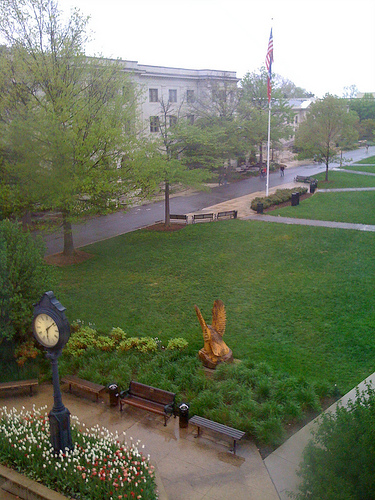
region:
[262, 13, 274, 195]
american flag at the top of a white flag pole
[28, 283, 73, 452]
clock in a park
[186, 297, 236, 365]
golden, winged sculpture in a park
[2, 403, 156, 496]
tiny pink, red, and white flowers near a clock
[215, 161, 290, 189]
people walking in the road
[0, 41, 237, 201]
trees partial obscuring a building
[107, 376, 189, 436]
two metal trash cans on either side of a wooden bench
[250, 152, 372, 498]
cement walkways throughout the park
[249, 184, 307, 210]
short, green bushes at the bottom of the flag pole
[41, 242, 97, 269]
wood chips around the base of a tree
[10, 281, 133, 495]
clock tower in flower bed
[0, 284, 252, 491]
park benches facing the tulips and clock tower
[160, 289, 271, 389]
gold American eagle statue in the park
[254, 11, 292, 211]
An American flag flying in the park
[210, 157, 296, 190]
people on campus walking to class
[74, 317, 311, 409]
landscape shrubs in the park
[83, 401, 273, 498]
the walkway is wet after rain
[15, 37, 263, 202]
large building on college campus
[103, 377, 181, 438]
ashtray next to the park bench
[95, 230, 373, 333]
green grass in the common area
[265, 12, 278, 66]
United States of America flag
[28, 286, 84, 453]
Black post with a clock at the top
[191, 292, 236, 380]
Wood carved eagle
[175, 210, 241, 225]
Row of benches on the sidewalk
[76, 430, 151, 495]
Flower bed with red, white and pink flowers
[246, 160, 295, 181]
People walking down the middle of a street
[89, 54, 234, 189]
Large white building with trees in front of it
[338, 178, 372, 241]
Sidewalks going thru middle of grass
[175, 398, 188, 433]
Tall black garbage can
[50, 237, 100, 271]
Landscaping around base of tall tree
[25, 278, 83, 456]
black clock with Roman numeral numbers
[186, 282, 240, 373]
brown eagle statue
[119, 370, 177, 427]
brown bench with black arms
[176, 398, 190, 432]
black trash can next to bench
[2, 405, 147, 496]
red and white flowers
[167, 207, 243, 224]
row of three benches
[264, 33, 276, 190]
flag pole with two flags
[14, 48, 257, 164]
building with a lot of windows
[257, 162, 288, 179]
people walking on asphalt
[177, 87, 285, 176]
trees in front of building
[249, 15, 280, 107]
United States of America flag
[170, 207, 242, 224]
row of three park benches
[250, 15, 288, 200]
red, white, and blue flag on white flagpole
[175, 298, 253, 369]
brown and orange statue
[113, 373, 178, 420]
brown and black park bench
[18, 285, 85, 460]
black clock with white face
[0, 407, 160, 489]
red, pink, and white flowers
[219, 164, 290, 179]
pedestrians walking on street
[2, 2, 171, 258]
light green tree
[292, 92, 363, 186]
light green tree